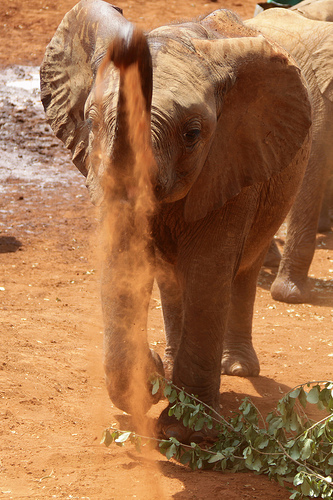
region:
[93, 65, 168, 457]
a cloud of dry dirt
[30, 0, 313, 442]
an elephant picking up dirt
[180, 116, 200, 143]
the eye of a dirty elephant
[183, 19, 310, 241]
the ear on an elephant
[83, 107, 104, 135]
an eye of the elephant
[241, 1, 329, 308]
an elephant walking behind an elephant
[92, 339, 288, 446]
the feet of an elephant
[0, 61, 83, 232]
a patch of wet dirt on the ground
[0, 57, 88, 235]
a patch of mud on the ground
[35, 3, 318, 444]
an elephant playing in the dirt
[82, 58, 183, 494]
dust stirred up by an elephant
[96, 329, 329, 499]
trunk picks up branches to eat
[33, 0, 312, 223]
this baby has the big ears of an African elephant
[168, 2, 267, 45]
hump on the back of the baby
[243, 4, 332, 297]
a second baby elephant stands in back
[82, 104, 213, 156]
eyes looking down at the ground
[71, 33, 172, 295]
the trunk of the baby drops the soil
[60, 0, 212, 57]
wet areas on ears and head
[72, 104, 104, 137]
elephant has long eyelashes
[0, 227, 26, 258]
a shadow on the ground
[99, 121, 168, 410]
trunk is long and full of dust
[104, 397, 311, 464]
elephant eating the grass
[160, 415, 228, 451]
feet of animal are large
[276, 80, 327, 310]
second animal in the back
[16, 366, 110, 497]
dirt on the ground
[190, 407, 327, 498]
leaves on the ground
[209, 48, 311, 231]
ears are big and gray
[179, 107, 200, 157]
eye is looking down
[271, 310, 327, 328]
stones on the ground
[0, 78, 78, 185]
rocks in the distance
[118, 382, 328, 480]
some granches on the ground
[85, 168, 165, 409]
the thick elephant's leg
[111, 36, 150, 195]
the elephant's trunk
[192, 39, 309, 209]
the elephant's big ear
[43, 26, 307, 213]
the head of the elephant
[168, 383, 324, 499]
the shadow of the elephant on the ground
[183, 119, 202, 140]
one eye of the elephant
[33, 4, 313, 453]
the elephant is playing with dust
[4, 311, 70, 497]
looks like a dry terrain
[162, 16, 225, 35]
the back of the big elephant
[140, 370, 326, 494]
greenery laying on the brown dirt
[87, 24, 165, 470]
elephant's trunk dropping soil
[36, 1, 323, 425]
elephant standing on brown dirt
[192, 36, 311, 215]
left ear of an elephant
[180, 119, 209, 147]
left eye of an elephant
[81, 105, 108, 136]
right eye of an elephant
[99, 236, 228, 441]
front legs of a gray elephant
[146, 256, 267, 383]
rear legs of a gray elephant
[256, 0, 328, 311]
dirt covered elephants in the background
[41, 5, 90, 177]
right ear of an elephant